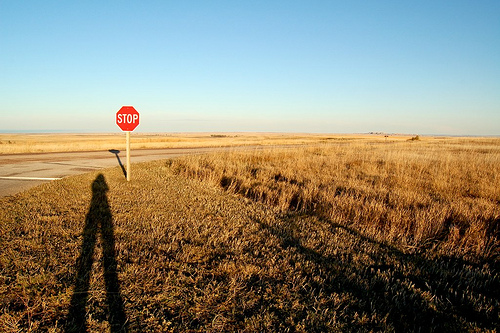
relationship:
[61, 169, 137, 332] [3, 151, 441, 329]
shadow on ground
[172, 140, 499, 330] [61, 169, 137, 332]
field next to shadow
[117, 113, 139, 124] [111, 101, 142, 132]
word on sign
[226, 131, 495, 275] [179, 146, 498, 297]
grass in field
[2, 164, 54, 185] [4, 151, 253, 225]
line on street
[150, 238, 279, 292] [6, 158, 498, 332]
shadow on grass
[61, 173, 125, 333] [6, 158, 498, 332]
shadow on grass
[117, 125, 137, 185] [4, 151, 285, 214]
pole on side of road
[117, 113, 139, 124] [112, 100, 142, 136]
word on sign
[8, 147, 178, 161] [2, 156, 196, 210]
dirt on road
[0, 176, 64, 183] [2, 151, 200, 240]
line on road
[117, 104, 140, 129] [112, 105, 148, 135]
word written on sign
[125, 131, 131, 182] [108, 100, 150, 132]
pole under sign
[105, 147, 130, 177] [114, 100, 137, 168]
shadow on sign